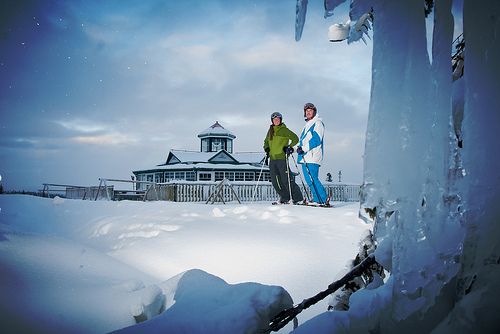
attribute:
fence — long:
[131, 155, 369, 223]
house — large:
[112, 115, 339, 206]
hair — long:
[303, 104, 310, 115]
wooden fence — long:
[105, 161, 287, 203]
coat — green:
[261, 120, 299, 161]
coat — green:
[293, 114, 330, 167]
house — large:
[130, 101, 280, 220]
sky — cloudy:
[68, 21, 258, 146]